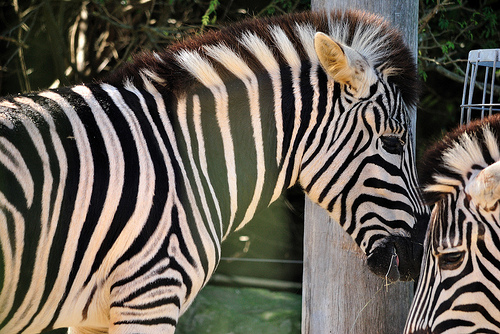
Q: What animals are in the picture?
A: Zebras.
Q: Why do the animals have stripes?
A: Because they are zebras.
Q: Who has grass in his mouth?
A: The zebra on the left.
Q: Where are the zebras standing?
A: Next to each other.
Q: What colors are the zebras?
A: Black and white.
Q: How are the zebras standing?
A: With their backs to the camera.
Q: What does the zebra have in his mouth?
A: Grass.